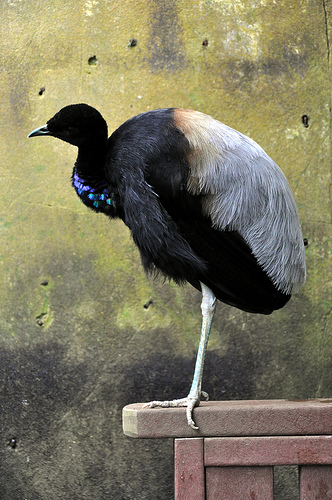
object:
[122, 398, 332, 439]
ledge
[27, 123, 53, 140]
beak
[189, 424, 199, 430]
claw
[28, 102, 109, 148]
head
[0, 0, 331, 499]
stained glass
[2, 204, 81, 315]
wall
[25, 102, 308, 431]
bird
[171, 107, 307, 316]
back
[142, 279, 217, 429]
white leg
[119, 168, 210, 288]
feather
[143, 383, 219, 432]
foot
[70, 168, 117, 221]
blocks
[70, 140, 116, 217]
(bird's)neck area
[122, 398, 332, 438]
wooden arm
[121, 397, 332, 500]
bench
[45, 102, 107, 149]
head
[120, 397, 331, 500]
ledge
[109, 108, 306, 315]
feathers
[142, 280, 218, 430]
leg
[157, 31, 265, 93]
shadow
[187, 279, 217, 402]
leg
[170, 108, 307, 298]
feathers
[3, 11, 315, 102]
glass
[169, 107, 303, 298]
plume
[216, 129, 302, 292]
plume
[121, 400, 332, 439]
brick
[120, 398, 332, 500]
stand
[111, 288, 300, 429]
shadow